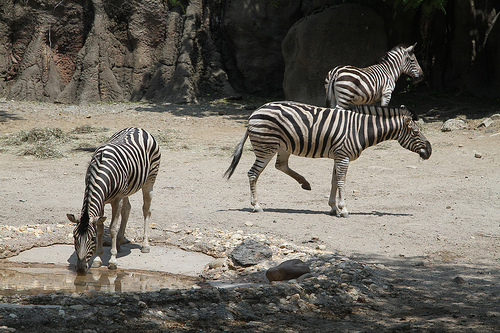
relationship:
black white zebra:
[66, 129, 161, 275] [65, 38, 435, 285]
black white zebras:
[66, 129, 161, 275] [65, 38, 435, 285]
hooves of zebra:
[247, 182, 353, 219] [65, 38, 435, 285]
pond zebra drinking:
[3, 237, 219, 304] [65, 213, 109, 271]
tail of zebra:
[223, 132, 255, 182] [225, 101, 433, 217]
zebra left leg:
[225, 101, 433, 217] [271, 139, 311, 192]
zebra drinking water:
[66, 129, 161, 275] [65, 213, 109, 271]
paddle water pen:
[3, 237, 219, 304] [3, 105, 499, 331]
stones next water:
[226, 238, 309, 280] [0, 237, 309, 307]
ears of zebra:
[67, 210, 109, 229] [66, 129, 161, 275]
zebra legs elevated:
[225, 101, 433, 217] [271, 139, 311, 192]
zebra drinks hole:
[66, 129, 161, 275] [3, 237, 219, 304]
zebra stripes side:
[225, 101, 433, 217] [245, 102, 434, 163]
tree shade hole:
[1, 253, 497, 332] [3, 237, 219, 304]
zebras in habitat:
[65, 38, 435, 285] [1, 1, 498, 331]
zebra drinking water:
[66, 129, 161, 275] [0, 237, 309, 307]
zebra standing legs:
[225, 101, 433, 217] [244, 151, 359, 213]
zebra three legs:
[225, 101, 433, 217] [244, 151, 359, 213]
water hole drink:
[0, 237, 309, 307] [65, 213, 109, 271]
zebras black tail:
[225, 101, 433, 217] [223, 132, 255, 182]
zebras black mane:
[225, 101, 433, 217] [349, 102, 414, 119]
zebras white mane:
[225, 101, 433, 217] [349, 102, 414, 119]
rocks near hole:
[198, 227, 359, 331] [3, 237, 219, 304]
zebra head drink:
[66, 129, 161, 275] [65, 213, 109, 271]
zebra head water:
[66, 129, 161, 275] [0, 237, 309, 307]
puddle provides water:
[3, 237, 219, 304] [0, 237, 309, 307]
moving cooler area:
[322, 44, 428, 109] [279, 0, 499, 115]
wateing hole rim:
[3, 237, 219, 304] [0, 217, 366, 332]